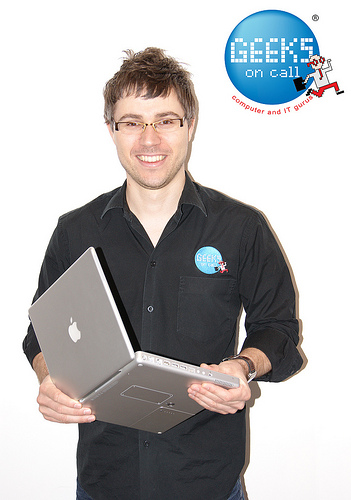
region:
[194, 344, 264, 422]
hand of a person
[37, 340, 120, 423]
hand of a person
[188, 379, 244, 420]
finger of a person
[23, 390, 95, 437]
finger of a person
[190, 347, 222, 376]
thumb of a person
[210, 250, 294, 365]
arm of a person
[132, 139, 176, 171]
mouth of a person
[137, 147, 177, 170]
teeth of a person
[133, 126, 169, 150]
nose of a person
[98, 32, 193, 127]
man has brown hair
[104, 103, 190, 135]
man is wearing glasses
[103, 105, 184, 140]
glasses have brown rim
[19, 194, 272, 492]
man has black shirt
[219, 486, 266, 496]
man has blue pants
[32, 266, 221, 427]
man is holding laptop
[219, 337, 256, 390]
man is wearing watch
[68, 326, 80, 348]
white logo on laptop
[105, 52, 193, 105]
man has brown hair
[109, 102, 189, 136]
man is wearing glasses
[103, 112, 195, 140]
black rim on glasses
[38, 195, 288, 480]
man has black shirt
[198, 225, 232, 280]
blue and white sticker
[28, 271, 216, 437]
grey and white laptop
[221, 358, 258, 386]
man is wearing watch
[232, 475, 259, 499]
man has blue pants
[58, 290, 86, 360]
white logo on laptop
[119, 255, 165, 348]
black buttons on shirt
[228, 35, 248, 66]
white letter on logo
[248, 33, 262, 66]
white letter on logo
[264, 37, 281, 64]
white letter on logo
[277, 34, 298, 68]
white letter on logo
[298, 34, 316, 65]
white letter on logo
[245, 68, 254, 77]
white letter on logo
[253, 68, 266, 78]
white letter on logo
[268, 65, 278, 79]
white letter on logo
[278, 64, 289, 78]
white letter on logo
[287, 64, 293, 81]
white letter on logo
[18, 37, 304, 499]
Man holding a laptop.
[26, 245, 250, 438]
Laptop in the hands.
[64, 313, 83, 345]
Apple logo on the computer.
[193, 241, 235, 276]
Logo on the shirt.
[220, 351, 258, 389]
Watch on the wrist.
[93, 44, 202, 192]
Glasses on the man.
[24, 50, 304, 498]
black shirt on the man.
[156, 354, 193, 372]
Usb ports on the computer.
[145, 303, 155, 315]
Button on the shirt.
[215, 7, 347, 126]
Sign on the wall.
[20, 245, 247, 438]
laptop has a apple on it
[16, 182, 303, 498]
geek squad patch on the black shirt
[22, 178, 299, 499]
button up shirt is black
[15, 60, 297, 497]
man is wearing glasses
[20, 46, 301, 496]
mans hair is messy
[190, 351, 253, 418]
watch is on mans wrist